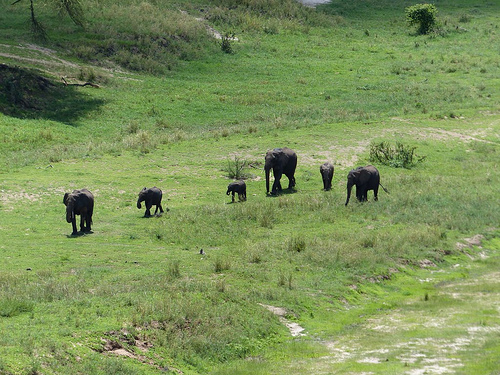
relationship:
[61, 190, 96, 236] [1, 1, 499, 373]
elephant on grass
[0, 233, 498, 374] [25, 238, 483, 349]
grass. on ground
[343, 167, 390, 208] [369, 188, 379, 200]
elephant has leg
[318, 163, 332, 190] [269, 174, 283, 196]
elephant has leg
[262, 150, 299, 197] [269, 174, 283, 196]
elephant has leg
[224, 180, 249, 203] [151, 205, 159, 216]
elephant has leg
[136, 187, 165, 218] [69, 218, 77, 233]
elephant has leg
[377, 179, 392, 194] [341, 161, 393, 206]
tail of elephant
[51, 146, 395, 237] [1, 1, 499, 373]
elephants on grass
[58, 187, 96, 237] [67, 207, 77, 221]
elephant has tusks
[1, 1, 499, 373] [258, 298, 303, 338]
grass with barren patch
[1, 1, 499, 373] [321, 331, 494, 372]
grass with barren patch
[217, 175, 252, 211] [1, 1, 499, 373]
elephant on grass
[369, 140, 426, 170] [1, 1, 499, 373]
shrub on grass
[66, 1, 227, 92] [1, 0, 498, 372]
branch on ground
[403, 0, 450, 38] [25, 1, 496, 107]
bush in background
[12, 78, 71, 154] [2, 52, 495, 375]
shadow on ground